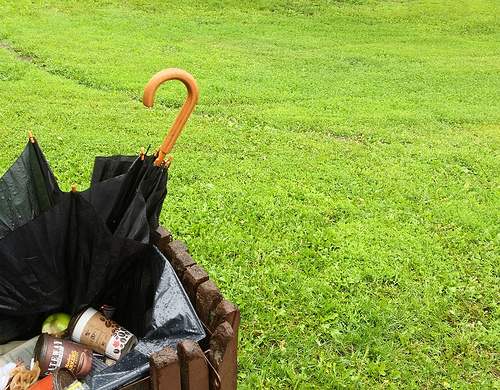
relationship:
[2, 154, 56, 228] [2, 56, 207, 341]
drops on umbrella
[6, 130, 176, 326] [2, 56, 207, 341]
canopy of umbrella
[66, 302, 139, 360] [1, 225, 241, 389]
coffee cup lying inside trash bin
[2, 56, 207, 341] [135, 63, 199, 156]
umbrella has hook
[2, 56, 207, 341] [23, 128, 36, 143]
umbrella has spoke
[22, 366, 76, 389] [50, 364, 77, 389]
cup has lid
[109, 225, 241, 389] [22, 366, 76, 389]
trash bin has cup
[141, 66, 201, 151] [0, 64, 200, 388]
handle of umbrella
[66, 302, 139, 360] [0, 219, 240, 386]
coffee cup in trash can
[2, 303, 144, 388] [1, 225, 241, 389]
trash in trash bin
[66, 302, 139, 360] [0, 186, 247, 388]
coffee cup in trash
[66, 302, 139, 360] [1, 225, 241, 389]
coffee cup in trash bin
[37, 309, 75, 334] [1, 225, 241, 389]
apple in trash bin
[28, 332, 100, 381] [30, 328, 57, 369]
cofee cup has lid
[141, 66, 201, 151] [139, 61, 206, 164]
handle has umbrella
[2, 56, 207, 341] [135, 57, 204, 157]
umbrella has handle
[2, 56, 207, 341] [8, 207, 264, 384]
umbrella on a trash can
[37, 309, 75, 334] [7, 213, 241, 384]
apple in trash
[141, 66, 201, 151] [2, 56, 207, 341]
handle on umbrella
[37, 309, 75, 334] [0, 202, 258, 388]
apple in bin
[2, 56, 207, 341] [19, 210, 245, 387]
umbrella in bin